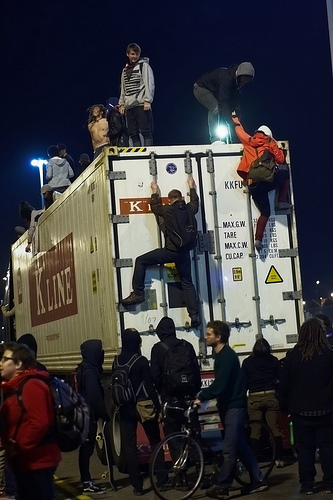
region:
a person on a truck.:
[119, 179, 217, 332]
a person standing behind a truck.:
[196, 305, 256, 491]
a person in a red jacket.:
[0, 322, 60, 494]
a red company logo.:
[17, 220, 93, 335]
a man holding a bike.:
[183, 311, 266, 491]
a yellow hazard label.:
[254, 261, 294, 297]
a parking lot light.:
[14, 146, 64, 225]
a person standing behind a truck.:
[272, 319, 330, 495]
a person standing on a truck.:
[37, 140, 76, 204]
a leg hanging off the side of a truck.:
[22, 179, 72, 259]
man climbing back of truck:
[121, 175, 208, 330]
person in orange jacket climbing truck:
[223, 100, 306, 260]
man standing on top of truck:
[116, 36, 171, 150]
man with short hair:
[118, 42, 165, 147]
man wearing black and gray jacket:
[116, 39, 165, 151]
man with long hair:
[82, 102, 119, 170]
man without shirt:
[80, 101, 119, 158]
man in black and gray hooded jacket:
[188, 55, 265, 146]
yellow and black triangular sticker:
[260, 264, 287, 288]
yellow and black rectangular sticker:
[229, 264, 245, 285]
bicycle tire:
[148, 430, 207, 498]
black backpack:
[152, 337, 200, 395]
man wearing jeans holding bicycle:
[146, 318, 278, 498]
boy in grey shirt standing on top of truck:
[115, 39, 156, 146]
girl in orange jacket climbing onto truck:
[227, 108, 294, 250]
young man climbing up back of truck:
[121, 172, 202, 329]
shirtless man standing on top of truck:
[84, 101, 108, 160]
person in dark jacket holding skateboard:
[70, 336, 118, 494]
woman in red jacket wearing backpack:
[1, 338, 93, 498]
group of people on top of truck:
[7, 139, 76, 255]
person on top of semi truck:
[115, 43, 158, 147]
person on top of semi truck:
[83, 104, 111, 151]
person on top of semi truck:
[37, 148, 74, 192]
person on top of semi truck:
[200, 59, 237, 143]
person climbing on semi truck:
[122, 188, 205, 326]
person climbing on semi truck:
[225, 116, 292, 246]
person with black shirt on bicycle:
[163, 325, 267, 491]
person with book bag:
[0, 350, 84, 487]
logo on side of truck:
[17, 249, 93, 327]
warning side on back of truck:
[257, 264, 285, 285]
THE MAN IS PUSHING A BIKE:
[145, 396, 280, 498]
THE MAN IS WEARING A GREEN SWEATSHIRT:
[191, 342, 249, 409]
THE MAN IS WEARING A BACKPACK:
[50, 371, 97, 457]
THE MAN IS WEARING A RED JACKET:
[0, 374, 72, 481]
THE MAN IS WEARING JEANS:
[204, 401, 262, 492]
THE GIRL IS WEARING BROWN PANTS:
[243, 390, 289, 474]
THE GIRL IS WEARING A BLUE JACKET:
[239, 352, 283, 397]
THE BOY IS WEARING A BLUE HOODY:
[111, 323, 159, 420]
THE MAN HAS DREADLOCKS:
[294, 314, 332, 364]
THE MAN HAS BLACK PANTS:
[291, 409, 331, 495]